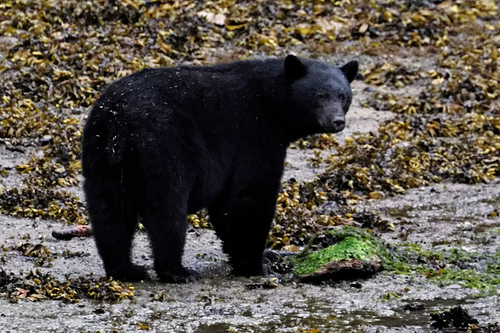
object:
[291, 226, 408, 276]
moss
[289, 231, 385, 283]
rock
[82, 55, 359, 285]
back